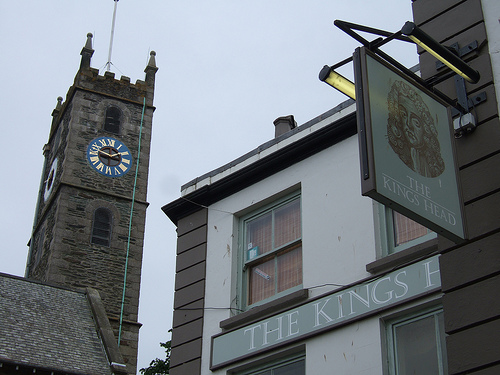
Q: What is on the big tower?
A: Clock.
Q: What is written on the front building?
A: THE KINGS.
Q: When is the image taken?
A: In the evening.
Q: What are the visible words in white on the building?
A: The kings.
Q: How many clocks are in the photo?
A: One.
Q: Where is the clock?
A: Side of steeple.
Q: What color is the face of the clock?
A: Black and gold.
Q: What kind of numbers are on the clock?
A: Roman numerals.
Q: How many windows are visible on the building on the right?
A: Four.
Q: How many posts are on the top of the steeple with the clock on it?
A: Four.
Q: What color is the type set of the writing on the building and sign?
A: White.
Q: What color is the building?
A: Brown and white.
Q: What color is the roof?
A: Gray.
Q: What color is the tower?
A: Brown.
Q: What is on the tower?
A: Clock.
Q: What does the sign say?
A: The kings head.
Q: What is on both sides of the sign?
A: Lights.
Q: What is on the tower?
A: Clock.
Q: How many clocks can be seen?
A: Two.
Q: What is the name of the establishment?
A: The Kings Head.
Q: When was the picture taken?
A: 1:45.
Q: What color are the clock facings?
A: Blue.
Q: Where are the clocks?
A: On the sides of the tower.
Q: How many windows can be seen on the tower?
A: 4.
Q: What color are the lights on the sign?
A: Yellow.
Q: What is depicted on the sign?
A: A man's head.